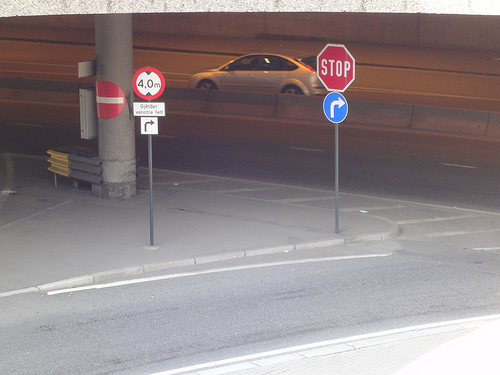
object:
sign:
[315, 44, 357, 92]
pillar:
[96, 13, 136, 202]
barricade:
[44, 143, 111, 186]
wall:
[344, 15, 490, 44]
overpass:
[361, 95, 498, 137]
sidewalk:
[319, 324, 472, 372]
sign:
[94, 80, 124, 119]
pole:
[146, 135, 155, 246]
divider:
[42, 146, 105, 194]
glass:
[239, 55, 286, 70]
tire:
[196, 78, 218, 92]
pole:
[332, 125, 342, 233]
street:
[146, 260, 494, 316]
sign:
[136, 117, 160, 135]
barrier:
[44, 144, 106, 195]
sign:
[133, 102, 166, 116]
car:
[189, 53, 332, 98]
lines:
[44, 248, 392, 296]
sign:
[322, 92, 351, 124]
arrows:
[328, 97, 345, 119]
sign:
[130, 65, 167, 100]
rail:
[44, 149, 102, 184]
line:
[439, 161, 477, 170]